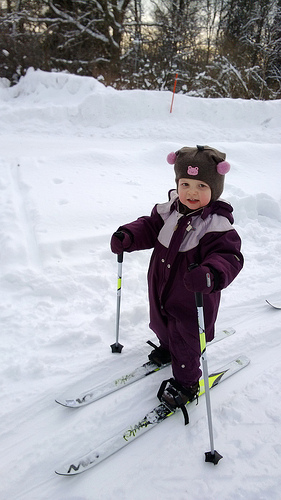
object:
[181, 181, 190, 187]
right eye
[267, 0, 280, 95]
trees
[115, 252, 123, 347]
pole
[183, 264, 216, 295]
glove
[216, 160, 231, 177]
ball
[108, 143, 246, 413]
child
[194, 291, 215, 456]
ski pole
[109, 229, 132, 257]
glove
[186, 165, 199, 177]
design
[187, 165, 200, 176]
bear head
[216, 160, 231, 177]
pompom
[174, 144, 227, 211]
head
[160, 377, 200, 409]
boot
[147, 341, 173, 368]
boot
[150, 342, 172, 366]
foot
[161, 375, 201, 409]
foot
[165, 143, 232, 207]
hat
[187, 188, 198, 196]
nose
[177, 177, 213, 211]
face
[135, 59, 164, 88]
wall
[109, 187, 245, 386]
snow suit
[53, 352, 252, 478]
skis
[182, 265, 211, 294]
hand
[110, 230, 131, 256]
hand